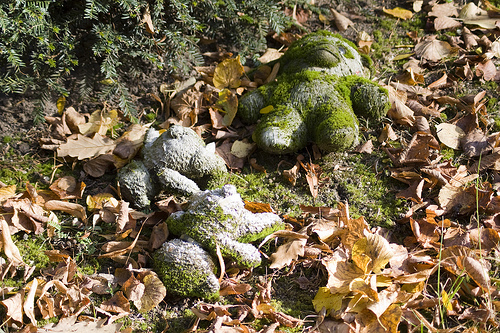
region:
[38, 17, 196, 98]
Evergreen tree, pine or furr like a christmas tree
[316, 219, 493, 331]
Leaves and Grass together, late summer or early fall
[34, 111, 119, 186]
Dried leaves from a maple tree perhaps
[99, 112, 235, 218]
Stuffed bear upside down abandoned to nature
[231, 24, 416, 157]
Perhaps covered in moss, this toy has been outside for a while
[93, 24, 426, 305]
Three stuffed animals have been left outside too long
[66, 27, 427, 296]
This yard belonged to a family with young children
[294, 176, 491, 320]
This yard needs to be raked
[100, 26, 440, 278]
This yard has not been raked in a long time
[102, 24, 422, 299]
Three stuffed bears lay in this yard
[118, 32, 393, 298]
discarded toys in the woods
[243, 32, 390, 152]
toy with green growth on it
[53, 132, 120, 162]
dried leaf on the ground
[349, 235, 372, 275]
a yellow leaf on the ground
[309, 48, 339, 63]
the mouth of the toy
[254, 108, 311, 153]
right leg of the toy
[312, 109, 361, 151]
left leg of the toy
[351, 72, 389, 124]
left arm of the couch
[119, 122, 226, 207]
stuffed animal laying face down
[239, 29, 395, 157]
stuffed animal laying face up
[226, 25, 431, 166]
This is some algae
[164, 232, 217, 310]
This is some algae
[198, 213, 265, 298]
This is some algae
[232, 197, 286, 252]
This is some algae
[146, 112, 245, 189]
This is some algae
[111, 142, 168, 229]
This is some algae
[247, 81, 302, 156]
This is some algae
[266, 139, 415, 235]
This is some algae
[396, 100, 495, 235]
These are fallen leaves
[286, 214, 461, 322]
These are fallen leaves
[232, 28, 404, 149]
Stuffed animal on the ground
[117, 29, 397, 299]
Stuffed animals on the ground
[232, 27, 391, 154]
Doll is on the ground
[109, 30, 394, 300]
Dolls are on the ground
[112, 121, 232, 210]
White stuffed animal on the ground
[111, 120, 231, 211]
White doll on the ground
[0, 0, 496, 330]
Leaves on the ground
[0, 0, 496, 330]
Dead leaves on the ground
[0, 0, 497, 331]
Brown leaves on the ground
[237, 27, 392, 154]
Stuffed animal covered in moss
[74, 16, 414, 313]
Stuffed animals in the woods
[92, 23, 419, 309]
forgotten stuffed animals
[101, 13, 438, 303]
Stuffed animals with moss on them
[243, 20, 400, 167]
A stuffed animal covered in green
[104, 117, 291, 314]
Two stuffed animals on the ground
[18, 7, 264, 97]
Greenery on the ground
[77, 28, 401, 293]
Dirty stuffed animals on the ground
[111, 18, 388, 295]
Old stuffed animals laying in leaves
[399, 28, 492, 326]
Leaves in the ground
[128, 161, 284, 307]
An old stuffed bear face down